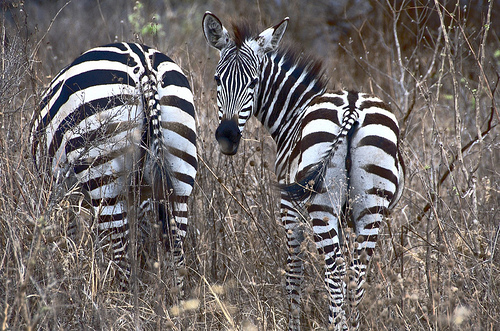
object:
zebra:
[200, 9, 408, 331]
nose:
[215, 121, 242, 142]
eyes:
[213, 75, 222, 87]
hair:
[267, 160, 326, 203]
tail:
[272, 109, 359, 203]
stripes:
[299, 130, 336, 167]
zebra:
[27, 40, 201, 304]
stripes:
[32, 69, 138, 173]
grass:
[0, 76, 499, 330]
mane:
[231, 16, 342, 92]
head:
[201, 9, 290, 155]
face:
[213, 66, 260, 157]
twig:
[401, 77, 499, 242]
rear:
[300, 90, 400, 200]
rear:
[66, 41, 199, 182]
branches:
[390, 1, 409, 121]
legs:
[74, 158, 131, 298]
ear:
[255, 16, 289, 51]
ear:
[201, 10, 230, 49]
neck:
[259, 51, 327, 136]